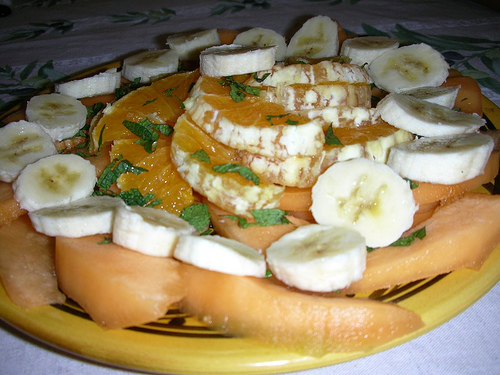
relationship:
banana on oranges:
[200, 42, 275, 78] [117, 92, 292, 197]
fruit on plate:
[2, 45, 477, 294] [2, 45, 499, 373]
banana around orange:
[22, 150, 415, 290] [97, 57, 415, 220]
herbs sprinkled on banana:
[95, 103, 287, 241] [265, 225, 367, 294]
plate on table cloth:
[2, 45, 499, 373] [0, 3, 498, 88]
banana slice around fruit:
[11, 153, 98, 213] [167, 111, 285, 219]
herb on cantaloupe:
[397, 226, 437, 252] [365, 198, 498, 289]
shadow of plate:
[2, 310, 152, 373] [5, 237, 497, 372]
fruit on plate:
[57, 236, 181, 331] [2, 45, 499, 373]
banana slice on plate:
[27, 195, 123, 237] [2, 45, 499, 373]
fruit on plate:
[186, 68, 322, 155] [2, 45, 499, 373]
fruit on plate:
[91, 71, 197, 216] [2, 45, 499, 373]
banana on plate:
[265, 225, 367, 294] [2, 45, 499, 373]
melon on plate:
[175, 263, 424, 356] [2, 45, 499, 373]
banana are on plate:
[307, 158, 416, 248] [9, 286, 487, 373]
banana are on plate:
[366, 42, 450, 94] [9, 286, 487, 373]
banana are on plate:
[171, 235, 267, 278] [9, 286, 487, 373]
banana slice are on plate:
[11, 153, 98, 213] [9, 286, 487, 373]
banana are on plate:
[198, 42, 278, 77] [9, 286, 487, 373]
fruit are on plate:
[109, 137, 193, 221] [9, 286, 487, 373]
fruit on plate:
[51, 236, 186, 331] [9, 286, 487, 373]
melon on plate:
[190, 288, 420, 339] [9, 286, 487, 373]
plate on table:
[2, 45, 499, 373] [8, 16, 113, 70]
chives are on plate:
[122, 110, 172, 163] [2, 45, 499, 373]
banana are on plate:
[375, 92, 486, 138] [2, 45, 499, 373]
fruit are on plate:
[183, 74, 326, 159] [2, 45, 499, 373]